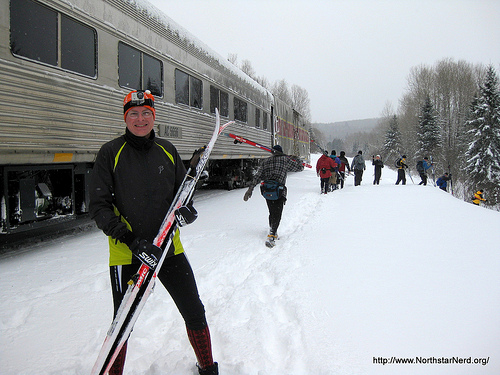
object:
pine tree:
[462, 66, 499, 201]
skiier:
[88, 89, 220, 374]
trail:
[0, 154, 498, 372]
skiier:
[372, 155, 384, 186]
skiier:
[394, 155, 408, 186]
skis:
[92, 108, 234, 375]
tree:
[414, 94, 443, 187]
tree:
[379, 113, 405, 169]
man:
[244, 145, 304, 249]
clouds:
[153, 0, 499, 124]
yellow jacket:
[472, 191, 486, 204]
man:
[472, 189, 487, 205]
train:
[0, 0, 311, 255]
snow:
[127, 0, 272, 95]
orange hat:
[123, 90, 155, 123]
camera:
[131, 92, 145, 104]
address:
[371, 356, 491, 366]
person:
[316, 150, 338, 194]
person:
[326, 149, 341, 192]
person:
[337, 151, 350, 190]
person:
[351, 150, 366, 186]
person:
[372, 154, 384, 185]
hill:
[306, 118, 498, 156]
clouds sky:
[150, 0, 500, 125]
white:
[413, 245, 468, 280]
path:
[0, 152, 500, 374]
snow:
[3, 152, 498, 375]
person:
[416, 157, 434, 186]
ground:
[0, 153, 499, 375]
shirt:
[249, 155, 304, 200]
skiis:
[229, 133, 312, 168]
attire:
[89, 126, 215, 370]